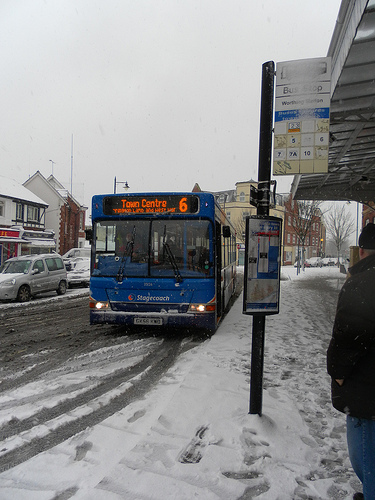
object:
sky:
[1, 2, 374, 241]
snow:
[1, 267, 360, 498]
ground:
[2, 255, 374, 499]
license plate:
[132, 315, 162, 327]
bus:
[86, 191, 241, 334]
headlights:
[192, 301, 205, 315]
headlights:
[90, 302, 106, 312]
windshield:
[89, 214, 219, 285]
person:
[324, 219, 374, 500]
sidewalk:
[88, 275, 373, 499]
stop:
[87, 1, 373, 500]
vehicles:
[1, 251, 69, 308]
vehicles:
[66, 256, 93, 288]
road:
[3, 255, 251, 497]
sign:
[235, 213, 288, 324]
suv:
[56, 242, 88, 276]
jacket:
[324, 257, 375, 420]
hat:
[355, 222, 374, 250]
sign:
[270, 57, 333, 179]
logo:
[133, 294, 172, 303]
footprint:
[220, 467, 260, 481]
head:
[353, 223, 374, 265]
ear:
[353, 244, 364, 256]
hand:
[329, 371, 345, 386]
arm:
[324, 276, 365, 384]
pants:
[342, 409, 374, 500]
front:
[89, 192, 217, 328]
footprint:
[235, 480, 273, 499]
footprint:
[240, 449, 272, 465]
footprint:
[243, 434, 272, 450]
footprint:
[69, 437, 94, 464]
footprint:
[45, 482, 80, 500]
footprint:
[127, 406, 149, 426]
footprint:
[324, 481, 351, 500]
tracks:
[175, 421, 218, 468]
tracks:
[2, 332, 189, 472]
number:
[178, 195, 189, 213]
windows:
[26, 205, 43, 224]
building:
[1, 173, 60, 280]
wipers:
[161, 240, 185, 283]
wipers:
[114, 240, 134, 278]